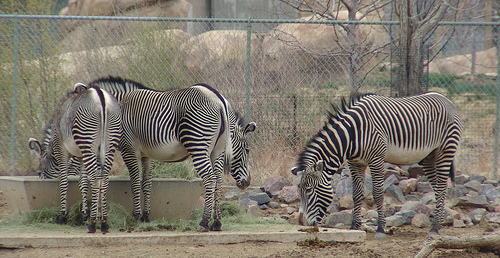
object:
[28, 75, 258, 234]
zebras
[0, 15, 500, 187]
fence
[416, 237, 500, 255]
branch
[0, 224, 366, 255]
concrete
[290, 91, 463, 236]
zebra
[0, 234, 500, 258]
ground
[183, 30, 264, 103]
rock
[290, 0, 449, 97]
tree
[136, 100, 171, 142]
stripes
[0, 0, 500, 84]
rocks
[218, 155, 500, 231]
rocks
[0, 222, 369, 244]
platform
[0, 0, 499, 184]
hay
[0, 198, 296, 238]
hay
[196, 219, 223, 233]
feet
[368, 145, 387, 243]
leg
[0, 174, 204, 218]
trough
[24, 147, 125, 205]
feeding